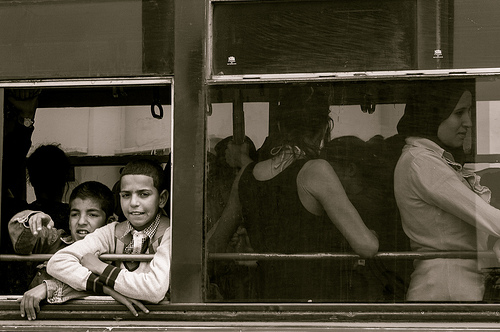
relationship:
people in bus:
[2, 78, 499, 324] [2, 67, 497, 327]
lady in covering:
[375, 51, 483, 248] [396, 64, 471, 134]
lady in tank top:
[214, 88, 394, 323] [238, 143, 343, 300]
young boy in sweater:
[44, 162, 171, 304] [46, 214, 173, 303]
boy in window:
[7, 181, 119, 322] [2, 85, 170, 307]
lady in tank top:
[206, 83, 378, 303] [240, 150, 335, 296]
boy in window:
[47, 162, 173, 317] [1, 69, 203, 314]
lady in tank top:
[206, 83, 378, 303] [225, 150, 345, 307]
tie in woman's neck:
[262, 138, 309, 173] [270, 136, 327, 156]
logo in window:
[226, 54, 236, 65] [210, 2, 498, 74]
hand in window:
[29, 209, 59, 242] [2, 85, 170, 307]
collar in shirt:
[109, 218, 166, 244] [42, 207, 172, 302]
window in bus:
[206, 87, 497, 302] [1, 0, 498, 330]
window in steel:
[206, 87, 497, 302] [207, 247, 497, 262]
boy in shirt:
[43, 162, 177, 318] [48, 214, 169, 303]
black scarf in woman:
[396, 76, 477, 140] [393, 74, 499, 303]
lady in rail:
[206, 83, 378, 303] [3, 247, 499, 264]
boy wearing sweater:
[47, 162, 173, 317] [49, 223, 179, 312]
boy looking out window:
[46, 156, 173, 314] [2, 71, 178, 315]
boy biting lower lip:
[46, 156, 173, 314] [127, 210, 147, 215]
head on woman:
[394, 75, 476, 150] [393, 74, 499, 303]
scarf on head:
[393, 76, 473, 169] [394, 75, 476, 150]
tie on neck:
[269, 137, 302, 172] [265, 134, 313, 163]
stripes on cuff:
[82, 273, 104, 300] [85, 261, 119, 294]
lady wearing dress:
[206, 83, 378, 303] [242, 158, 364, 316]